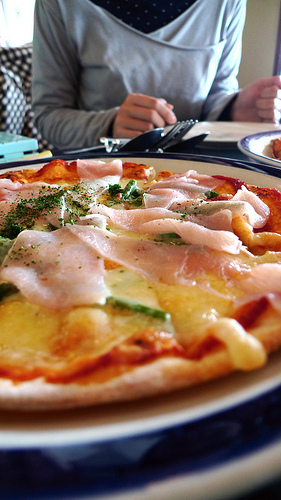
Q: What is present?
A: Food.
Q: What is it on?
A: A plate.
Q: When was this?
A: Daytime.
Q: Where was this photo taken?
A: At a restaurant.